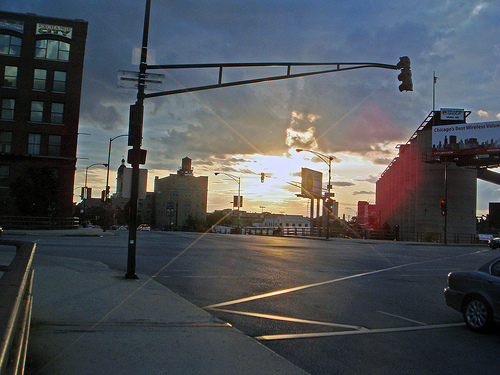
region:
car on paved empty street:
[441, 257, 498, 333]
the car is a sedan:
[442, 254, 498, 329]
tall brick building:
[0, 11, 86, 231]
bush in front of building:
[5, 163, 69, 217]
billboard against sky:
[295, 166, 324, 235]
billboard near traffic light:
[421, 122, 498, 164]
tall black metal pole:
[126, 1, 153, 278]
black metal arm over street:
[142, 61, 401, 98]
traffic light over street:
[396, 55, 414, 92]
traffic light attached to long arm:
[395, 54, 417, 91]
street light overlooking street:
[126, 1, 415, 281]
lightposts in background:
[189, 128, 349, 236]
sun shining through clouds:
[184, 78, 381, 210]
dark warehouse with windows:
[0, 20, 90, 228]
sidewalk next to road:
[21, 241, 301, 373]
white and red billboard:
[431, 118, 498, 164]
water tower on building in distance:
[149, 155, 219, 225]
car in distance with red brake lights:
[134, 222, 151, 233]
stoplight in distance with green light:
[101, 182, 113, 197]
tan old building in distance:
[155, 173, 209, 233]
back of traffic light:
[392, 55, 420, 92]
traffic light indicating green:
[103, 185, 112, 200]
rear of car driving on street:
[441, 249, 498, 331]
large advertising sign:
[431, 121, 498, 158]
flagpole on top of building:
[428, 67, 440, 110]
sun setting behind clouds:
[260, 146, 300, 191]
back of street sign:
[111, 67, 166, 91]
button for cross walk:
[126, 236, 138, 247]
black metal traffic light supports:
[165, 57, 393, 97]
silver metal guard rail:
[0, 236, 39, 373]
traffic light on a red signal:
[441, 196, 446, 214]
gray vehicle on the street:
[444, 253, 499, 333]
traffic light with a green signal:
[326, 198, 333, 215]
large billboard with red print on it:
[433, 123, 498, 158]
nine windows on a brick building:
[2, 71, 82, 228]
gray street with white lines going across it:
[293, 239, 450, 374]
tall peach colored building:
[153, 174, 207, 234]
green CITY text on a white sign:
[37, 23, 76, 35]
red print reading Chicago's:
[431, 125, 457, 134]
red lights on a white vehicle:
[139, 223, 150, 230]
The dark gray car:
[441, 251, 498, 350]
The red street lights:
[435, 195, 449, 220]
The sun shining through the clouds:
[227, 126, 324, 206]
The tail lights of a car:
[134, 221, 155, 233]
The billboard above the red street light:
[427, 118, 497, 168]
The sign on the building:
[436, 102, 466, 122]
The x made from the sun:
[30, 0, 450, 370]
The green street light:
[320, 200, 330, 217]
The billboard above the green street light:
[291, 162, 323, 204]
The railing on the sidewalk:
[1, 238, 40, 373]